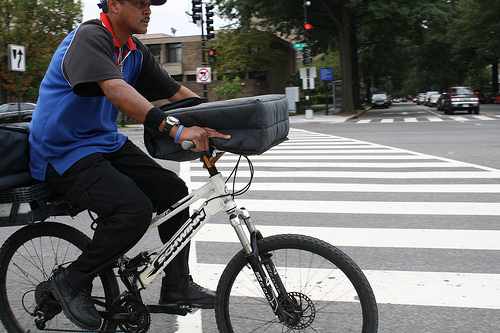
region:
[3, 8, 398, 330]
This is a pizza man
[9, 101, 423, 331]
Delivering pizza with a bike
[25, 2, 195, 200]
He is out for delivery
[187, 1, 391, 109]
A street light there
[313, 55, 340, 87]
A directory for directions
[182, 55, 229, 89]
A sign for drivers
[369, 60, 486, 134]
Cars are waiting to go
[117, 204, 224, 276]
Company logo for bike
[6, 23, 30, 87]
A sign for more drivers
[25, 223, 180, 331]
He has black shoes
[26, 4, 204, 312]
Delivery person on bicycle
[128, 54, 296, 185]
Pizza pouch balanced on handlebars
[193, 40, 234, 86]
Stop light is red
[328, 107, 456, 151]
Cross walk has white lines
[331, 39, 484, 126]
Cars stopped to the right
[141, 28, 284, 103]
Building behind delivery person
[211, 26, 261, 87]
Green moss on building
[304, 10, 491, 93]
Street lined with trees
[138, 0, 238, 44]
Sky appear to be greyish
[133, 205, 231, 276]
SCHWINN is written on bike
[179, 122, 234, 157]
the hand of a man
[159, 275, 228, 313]
a black shoe on the man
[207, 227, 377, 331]
a black bicycle tire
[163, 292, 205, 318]
a bicycle pedal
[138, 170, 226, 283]
a white bicycle frame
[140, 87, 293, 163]
a black pizza bag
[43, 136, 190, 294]
a pair of black pants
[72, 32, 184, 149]
the arm of the man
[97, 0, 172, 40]
the head of the man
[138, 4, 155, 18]
the nose of the man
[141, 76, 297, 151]
a pizza resting on a handle bar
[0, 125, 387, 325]
a white with black Schwinn bike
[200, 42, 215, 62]
a red light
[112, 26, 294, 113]
a brown brick building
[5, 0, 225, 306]
a pizza delivery man riding a bike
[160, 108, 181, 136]
a watch on a wrist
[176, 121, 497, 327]
a crosswalk in a road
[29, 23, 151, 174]
a blue shirt on a man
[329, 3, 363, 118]
a tree alongside a road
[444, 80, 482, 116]
a truck on the road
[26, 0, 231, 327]
man on a bike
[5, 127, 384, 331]
white and black colored bike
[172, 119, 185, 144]
man's blue wrist band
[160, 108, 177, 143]
man's black colored wristwatch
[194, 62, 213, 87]
no left turn sign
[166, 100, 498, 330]
pedestrian cross walk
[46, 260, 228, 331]
pair of black shoes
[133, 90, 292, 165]
black bag on handlebars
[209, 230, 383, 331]
front tire of bike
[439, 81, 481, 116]
red truck at intersection